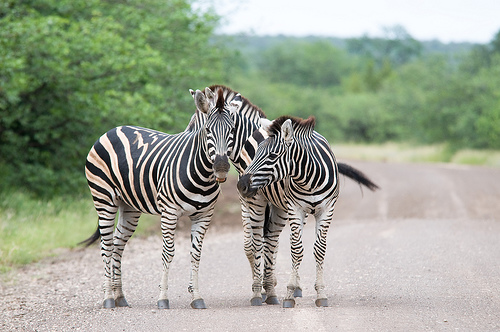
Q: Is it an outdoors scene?
A: Yes, it is outdoors.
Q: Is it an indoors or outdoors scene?
A: It is outdoors.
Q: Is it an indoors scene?
A: No, it is outdoors.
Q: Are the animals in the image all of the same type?
A: Yes, all the animals are zebras.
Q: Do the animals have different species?
A: No, all the animals are zebras.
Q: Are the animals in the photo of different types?
A: No, all the animals are zebras.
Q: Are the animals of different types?
A: No, all the animals are zebras.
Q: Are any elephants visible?
A: No, there are no elephants.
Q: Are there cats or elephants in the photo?
A: No, there are no elephants or cats.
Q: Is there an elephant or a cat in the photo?
A: No, there are no elephants or cats.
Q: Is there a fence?
A: No, there are no fences.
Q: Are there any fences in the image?
A: No, there are no fences.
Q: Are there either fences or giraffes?
A: No, there are no fences or giraffes.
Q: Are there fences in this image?
A: No, there are no fences.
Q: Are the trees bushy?
A: Yes, the trees are bushy.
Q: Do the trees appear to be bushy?
A: Yes, the trees are bushy.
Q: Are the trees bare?
A: No, the trees are bushy.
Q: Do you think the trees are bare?
A: No, the trees are bushy.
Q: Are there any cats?
A: No, there are no cats.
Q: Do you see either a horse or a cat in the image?
A: No, there are no cats or horses.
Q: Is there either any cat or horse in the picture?
A: No, there are no cats or horses.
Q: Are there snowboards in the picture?
A: No, there are no snowboards.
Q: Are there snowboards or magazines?
A: No, there are no snowboards or magazines.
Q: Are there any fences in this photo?
A: No, there are no fences.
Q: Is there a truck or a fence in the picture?
A: No, there are no fences or trucks.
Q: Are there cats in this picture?
A: No, there are no cats.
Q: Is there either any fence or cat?
A: No, there are no cats or fences.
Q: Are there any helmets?
A: No, there are no helmets.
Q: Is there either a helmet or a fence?
A: No, there are no helmets or fences.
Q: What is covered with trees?
A: The hill is covered with trees.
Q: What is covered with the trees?
A: The hill is covered with trees.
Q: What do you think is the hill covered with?
A: The hill is covered with trees.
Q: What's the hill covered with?
A: The hill is covered with trees.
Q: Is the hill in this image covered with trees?
A: Yes, the hill is covered with trees.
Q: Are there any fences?
A: No, there are no fences.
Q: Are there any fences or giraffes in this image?
A: No, there are no fences or giraffes.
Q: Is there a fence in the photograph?
A: No, there are no fences.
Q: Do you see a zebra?
A: Yes, there is a zebra.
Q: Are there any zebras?
A: Yes, there is a zebra.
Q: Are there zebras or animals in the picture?
A: Yes, there is a zebra.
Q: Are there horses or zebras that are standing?
A: Yes, the zebra is standing.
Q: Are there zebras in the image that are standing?
A: Yes, there is a zebra that is standing.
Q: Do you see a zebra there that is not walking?
A: Yes, there is a zebra that is standing .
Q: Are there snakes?
A: No, there are no snakes.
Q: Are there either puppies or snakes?
A: No, there are no snakes or puppies.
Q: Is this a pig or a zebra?
A: This is a zebra.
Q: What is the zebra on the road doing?
A: The zebra is standing.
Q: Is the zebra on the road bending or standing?
A: The zebra is standing.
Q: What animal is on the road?
A: The zebra is on the road.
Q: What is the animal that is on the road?
A: The animal is a zebra.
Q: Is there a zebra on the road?
A: Yes, there is a zebra on the road.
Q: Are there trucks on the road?
A: No, there is a zebra on the road.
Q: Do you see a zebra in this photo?
A: Yes, there is a zebra.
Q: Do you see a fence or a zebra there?
A: Yes, there is a zebra.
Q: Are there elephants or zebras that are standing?
A: Yes, the zebra is standing.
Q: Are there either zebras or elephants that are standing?
A: Yes, the zebra is standing.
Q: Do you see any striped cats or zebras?
A: Yes, there is a striped zebra.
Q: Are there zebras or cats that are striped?
A: Yes, the zebra is striped.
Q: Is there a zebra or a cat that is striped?
A: Yes, the zebra is striped.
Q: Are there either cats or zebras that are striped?
A: Yes, the zebra is striped.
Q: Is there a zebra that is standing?
A: Yes, there is a zebra that is standing.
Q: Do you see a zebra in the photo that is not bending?
A: Yes, there is a zebra that is standing .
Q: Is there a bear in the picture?
A: No, there are no bears.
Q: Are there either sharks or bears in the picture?
A: No, there are no bears or sharks.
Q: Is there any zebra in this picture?
A: Yes, there is a zebra.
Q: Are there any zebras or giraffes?
A: Yes, there is a zebra.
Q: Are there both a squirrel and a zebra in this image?
A: No, there is a zebra but no squirrels.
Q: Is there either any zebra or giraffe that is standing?
A: Yes, the zebra is standing.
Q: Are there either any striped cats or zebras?
A: Yes, there is a striped zebra.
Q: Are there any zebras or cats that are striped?
A: Yes, the zebra is striped.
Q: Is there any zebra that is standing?
A: Yes, there is a zebra that is standing.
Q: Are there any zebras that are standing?
A: Yes, there is a zebra that is standing.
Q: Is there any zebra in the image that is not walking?
A: Yes, there is a zebra that is standing.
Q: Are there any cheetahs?
A: No, there are no cheetahs.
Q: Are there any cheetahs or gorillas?
A: No, there are no cheetahs or gorillas.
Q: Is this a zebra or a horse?
A: This is a zebra.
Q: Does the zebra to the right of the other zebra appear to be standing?
A: Yes, the zebra is standing.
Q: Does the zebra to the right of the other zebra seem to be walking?
A: No, the zebra is standing.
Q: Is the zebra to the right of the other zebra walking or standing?
A: The zebra is standing.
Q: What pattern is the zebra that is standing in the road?
A: The zebra is striped.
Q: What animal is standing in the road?
A: The zebra is standing in the road.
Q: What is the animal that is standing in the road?
A: The animal is a zebra.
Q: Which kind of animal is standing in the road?
A: The animal is a zebra.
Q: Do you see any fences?
A: No, there are no fences.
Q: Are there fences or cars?
A: No, there are no fences or cars.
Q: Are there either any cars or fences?
A: No, there are no fences or cars.